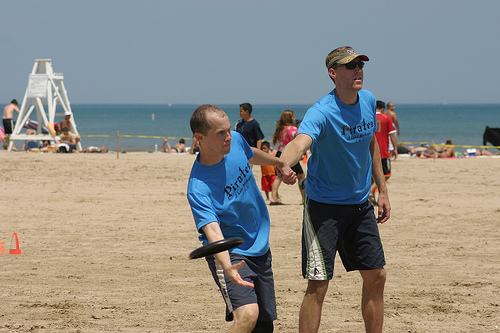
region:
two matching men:
[143, 63, 473, 312]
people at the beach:
[146, 31, 465, 318]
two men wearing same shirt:
[112, 42, 442, 298]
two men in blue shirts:
[192, 117, 474, 332]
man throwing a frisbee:
[137, 93, 331, 326]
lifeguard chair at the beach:
[18, 0, 153, 184]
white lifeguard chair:
[13, 0, 193, 178]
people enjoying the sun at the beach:
[76, 30, 496, 322]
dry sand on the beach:
[13, 143, 240, 330]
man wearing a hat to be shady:
[232, 18, 485, 264]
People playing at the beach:
[11, 22, 476, 329]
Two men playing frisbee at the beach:
[162, 29, 433, 302]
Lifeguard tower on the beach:
[6, 32, 132, 194]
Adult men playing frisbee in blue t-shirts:
[63, 40, 489, 325]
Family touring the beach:
[179, 79, 384, 191]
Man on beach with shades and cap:
[304, 32, 419, 325]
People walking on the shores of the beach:
[55, 36, 470, 266]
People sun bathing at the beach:
[11, 44, 478, 227]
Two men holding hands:
[101, 40, 462, 315]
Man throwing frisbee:
[140, 38, 480, 288]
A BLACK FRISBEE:
[171, 230, 251, 260]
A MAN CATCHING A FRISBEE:
[168, 97, 296, 329]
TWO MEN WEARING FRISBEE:
[166, 34, 423, 329]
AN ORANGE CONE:
[4, 226, 37, 268]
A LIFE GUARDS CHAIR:
[4, 47, 89, 160]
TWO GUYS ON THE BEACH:
[179, 31, 408, 331]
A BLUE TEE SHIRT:
[294, 83, 381, 213]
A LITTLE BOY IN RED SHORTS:
[249, 133, 284, 205]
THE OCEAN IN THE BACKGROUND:
[88, 97, 495, 174]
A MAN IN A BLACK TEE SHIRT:
[229, 94, 275, 153]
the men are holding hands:
[180, 42, 402, 331]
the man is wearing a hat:
[321, 44, 372, 76]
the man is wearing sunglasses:
[340, 60, 366, 75]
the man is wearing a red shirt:
[365, 107, 400, 164]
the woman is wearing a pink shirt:
[273, 125, 302, 158]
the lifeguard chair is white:
[4, 56, 88, 157]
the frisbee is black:
[185, 232, 246, 260]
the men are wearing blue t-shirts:
[179, 85, 386, 260]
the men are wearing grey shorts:
[194, 193, 387, 320]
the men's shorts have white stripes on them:
[211, 193, 330, 318]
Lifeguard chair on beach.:
[11, 52, 95, 157]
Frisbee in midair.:
[187, 223, 245, 269]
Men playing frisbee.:
[189, 45, 436, 331]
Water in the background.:
[2, 83, 495, 172]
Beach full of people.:
[7, 95, 492, 164]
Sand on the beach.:
[2, 147, 498, 332]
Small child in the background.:
[252, 141, 283, 200]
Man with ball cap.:
[323, 43, 373, 78]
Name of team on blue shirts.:
[189, 86, 384, 255]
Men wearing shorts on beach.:
[200, 196, 415, 328]